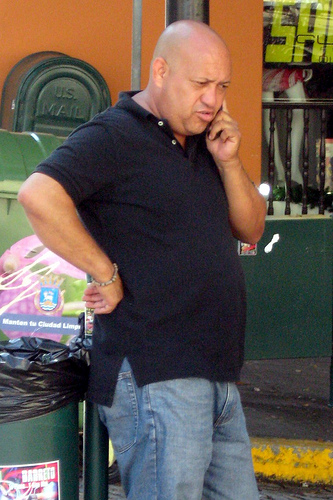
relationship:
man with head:
[32, 11, 268, 499] [148, 17, 230, 134]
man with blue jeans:
[32, 11, 268, 499] [100, 358, 263, 498]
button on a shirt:
[154, 117, 165, 126] [24, 85, 249, 410]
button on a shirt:
[169, 135, 176, 145] [24, 85, 249, 410]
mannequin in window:
[255, 60, 317, 191] [250, 64, 328, 137]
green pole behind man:
[82, 404, 111, 499] [32, 11, 268, 499]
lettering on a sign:
[268, 6, 332, 70] [4, 456, 64, 498]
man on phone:
[32, 11, 268, 499] [208, 103, 227, 142]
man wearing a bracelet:
[32, 11, 268, 499] [90, 261, 117, 287]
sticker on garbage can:
[1, 458, 85, 499] [1, 337, 88, 496]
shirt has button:
[26, 104, 264, 388] [171, 138, 178, 146]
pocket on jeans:
[99, 372, 140, 439] [98, 356, 261, 497]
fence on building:
[263, 98, 333, 216] [0, 1, 330, 398]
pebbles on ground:
[249, 383, 267, 394] [239, 358, 330, 498]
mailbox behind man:
[0, 49, 110, 136] [32, 11, 268, 499]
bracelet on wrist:
[93, 260, 118, 287] [80, 266, 118, 286]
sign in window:
[263, 1, 331, 63] [260, 1, 331, 201]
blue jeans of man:
[97, 358, 260, 500] [32, 11, 268, 499]